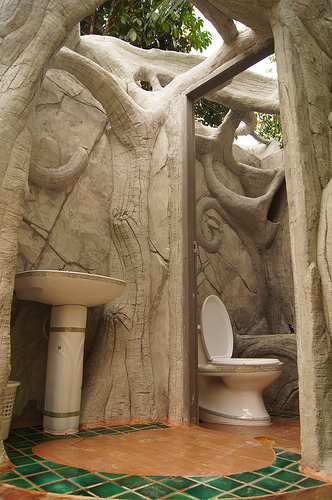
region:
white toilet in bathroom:
[197, 291, 279, 432]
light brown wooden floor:
[142, 429, 217, 475]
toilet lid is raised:
[198, 303, 229, 355]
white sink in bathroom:
[18, 265, 126, 319]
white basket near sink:
[0, 382, 47, 440]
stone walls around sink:
[19, 90, 152, 254]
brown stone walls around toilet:
[202, 156, 268, 306]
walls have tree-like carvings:
[197, 159, 280, 339]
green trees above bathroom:
[143, 48, 305, 127]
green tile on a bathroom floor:
[4, 419, 327, 499]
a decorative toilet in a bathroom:
[195, 293, 284, 430]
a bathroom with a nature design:
[0, 0, 331, 498]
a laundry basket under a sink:
[0, 377, 22, 441]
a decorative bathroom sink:
[13, 269, 128, 433]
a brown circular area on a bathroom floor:
[29, 421, 276, 477]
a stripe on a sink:
[47, 324, 87, 333]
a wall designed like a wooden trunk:
[76, 95, 190, 428]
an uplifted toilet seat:
[198, 292, 235, 361]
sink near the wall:
[13, 269, 125, 436]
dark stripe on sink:
[42, 409, 78, 415]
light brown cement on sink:
[42, 427, 79, 434]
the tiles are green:
[2, 421, 325, 498]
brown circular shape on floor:
[32, 426, 272, 474]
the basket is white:
[0, 381, 18, 438]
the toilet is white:
[196, 295, 281, 425]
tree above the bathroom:
[81, 0, 210, 54]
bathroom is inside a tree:
[1, 1, 331, 499]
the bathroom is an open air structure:
[8, 4, 328, 488]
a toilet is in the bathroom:
[195, 292, 286, 428]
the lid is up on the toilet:
[199, 292, 235, 360]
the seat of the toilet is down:
[210, 355, 280, 364]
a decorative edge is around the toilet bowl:
[198, 362, 282, 375]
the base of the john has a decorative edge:
[197, 390, 269, 423]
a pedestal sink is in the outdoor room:
[13, 268, 127, 436]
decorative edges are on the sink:
[16, 268, 126, 431]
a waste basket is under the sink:
[0, 379, 20, 440]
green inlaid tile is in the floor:
[6, 419, 322, 498]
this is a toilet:
[168, 278, 290, 460]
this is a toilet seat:
[188, 275, 233, 381]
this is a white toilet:
[195, 282, 296, 451]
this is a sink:
[10, 267, 183, 438]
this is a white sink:
[16, 259, 127, 430]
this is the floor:
[8, 421, 303, 497]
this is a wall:
[121, 264, 189, 409]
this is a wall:
[249, 268, 296, 340]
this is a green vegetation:
[106, 7, 232, 71]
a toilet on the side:
[197, 284, 284, 429]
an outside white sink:
[11, 241, 148, 431]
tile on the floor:
[5, 413, 312, 497]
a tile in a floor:
[109, 422, 132, 432]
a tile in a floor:
[110, 425, 132, 436]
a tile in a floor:
[90, 426, 116, 436]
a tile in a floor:
[57, 432, 76, 441]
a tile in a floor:
[25, 432, 54, 442]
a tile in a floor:
[7, 437, 34, 453]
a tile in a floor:
[9, 458, 43, 475]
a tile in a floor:
[24, 467, 61, 487]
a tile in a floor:
[33, 472, 69, 491]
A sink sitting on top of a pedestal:
[13, 268, 126, 308]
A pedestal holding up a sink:
[42, 305, 87, 434]